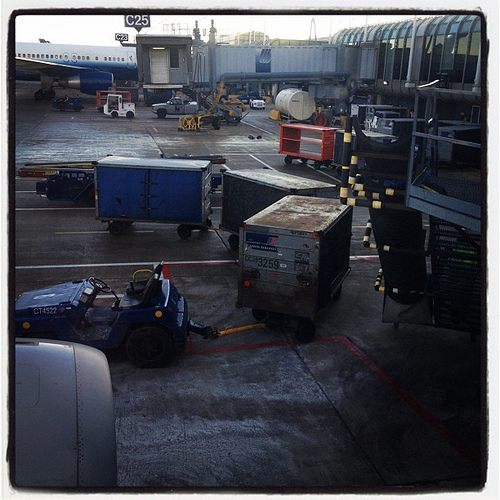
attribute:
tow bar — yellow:
[218, 320, 271, 340]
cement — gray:
[15, 96, 485, 488]